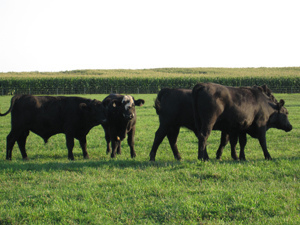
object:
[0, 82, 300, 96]
fence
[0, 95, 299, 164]
grassy area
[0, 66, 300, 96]
corn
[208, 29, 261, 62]
clouds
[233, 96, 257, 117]
fur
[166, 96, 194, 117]
fur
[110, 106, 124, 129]
fur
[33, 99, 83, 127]
fur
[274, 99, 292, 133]
head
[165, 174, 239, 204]
field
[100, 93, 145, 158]
black cow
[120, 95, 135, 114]
white face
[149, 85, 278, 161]
black cow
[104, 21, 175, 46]
blue sky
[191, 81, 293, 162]
cow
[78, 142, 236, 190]
field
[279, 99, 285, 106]
ear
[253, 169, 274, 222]
grass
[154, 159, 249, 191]
ground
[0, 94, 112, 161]
cow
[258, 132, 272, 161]
leg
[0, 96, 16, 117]
tail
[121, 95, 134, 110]
spot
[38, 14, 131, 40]
cloud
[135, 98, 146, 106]
ear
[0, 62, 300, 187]
pasture